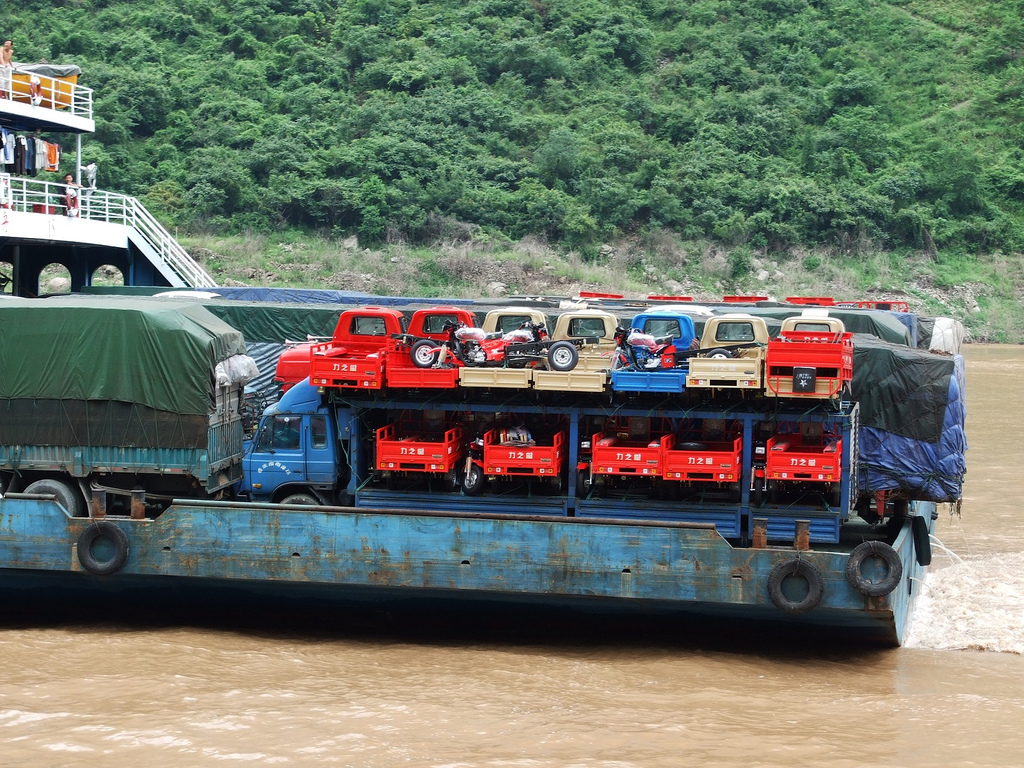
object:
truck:
[766, 306, 854, 399]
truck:
[236, 305, 858, 544]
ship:
[0, 58, 968, 646]